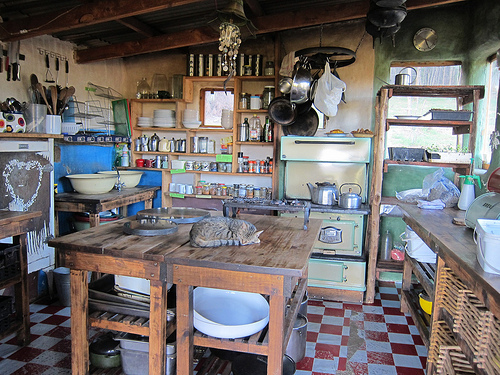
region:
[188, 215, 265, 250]
a sleeping grey and black striped cat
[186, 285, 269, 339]
a large white bowl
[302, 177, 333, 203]
a silver tea kettle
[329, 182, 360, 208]
a silver tea kettle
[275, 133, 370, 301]
an antique stove and oven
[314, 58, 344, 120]
a hanging white bag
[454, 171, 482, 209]
a green spray bottle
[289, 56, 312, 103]
a large metal hanging pot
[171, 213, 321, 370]
a wooden kitchen table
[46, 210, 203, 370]
a wooden kitchen table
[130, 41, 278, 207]
filled wooden shelves against kitchen wall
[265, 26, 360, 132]
hanging pots, pans and plastic bag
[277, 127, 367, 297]
old-fashioned stove and oven against wall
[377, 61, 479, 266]
open shelving with pans and containers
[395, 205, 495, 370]
wooden counter with shelves and baskets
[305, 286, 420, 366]
worn checkerboard tiles on floor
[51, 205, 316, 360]
wooden tables with shelves placed together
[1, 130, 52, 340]
white cabinet next to wooden table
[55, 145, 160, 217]
table with two large bowls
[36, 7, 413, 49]
wood beams slanted across ceiling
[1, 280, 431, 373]
a red and white checkered floor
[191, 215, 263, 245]
a cat sleeping on a counter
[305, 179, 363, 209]
two silver kettles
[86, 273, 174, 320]
baking sheets on a shelf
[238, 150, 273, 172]
several spices on a shelf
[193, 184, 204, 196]
a jar with a red lid on the counter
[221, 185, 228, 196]
a small jar with a yellow lid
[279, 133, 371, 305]
a stove with light green accents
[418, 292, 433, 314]
a yellow bowl on a bottom shelf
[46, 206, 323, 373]
a wooden kitchen island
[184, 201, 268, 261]
a cat sleeping on a table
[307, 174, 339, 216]
a silver tea pot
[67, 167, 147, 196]
two metal pans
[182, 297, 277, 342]
a large white bowl on a shelf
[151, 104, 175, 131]
a stack of white plates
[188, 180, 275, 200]
several glass jars on a shelf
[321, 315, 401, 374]
a red and white tile floor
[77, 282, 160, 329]
baking pans on a shelf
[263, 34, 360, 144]
pots and pans hanging from rack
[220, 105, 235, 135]
a stack of white bowls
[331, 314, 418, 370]
floor is red and white checkered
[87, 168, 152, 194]
sink has two large basins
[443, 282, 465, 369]
wooden crates on the shelves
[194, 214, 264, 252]
cat lying on the table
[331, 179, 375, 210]
teapot on the stove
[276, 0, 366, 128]
pan rack hanging from the ceiling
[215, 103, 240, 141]
stack of bowls on the shelf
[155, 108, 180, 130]
stack of plates on the shelf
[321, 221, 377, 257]
door to the oven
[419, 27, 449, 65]
clock hanging on the wall